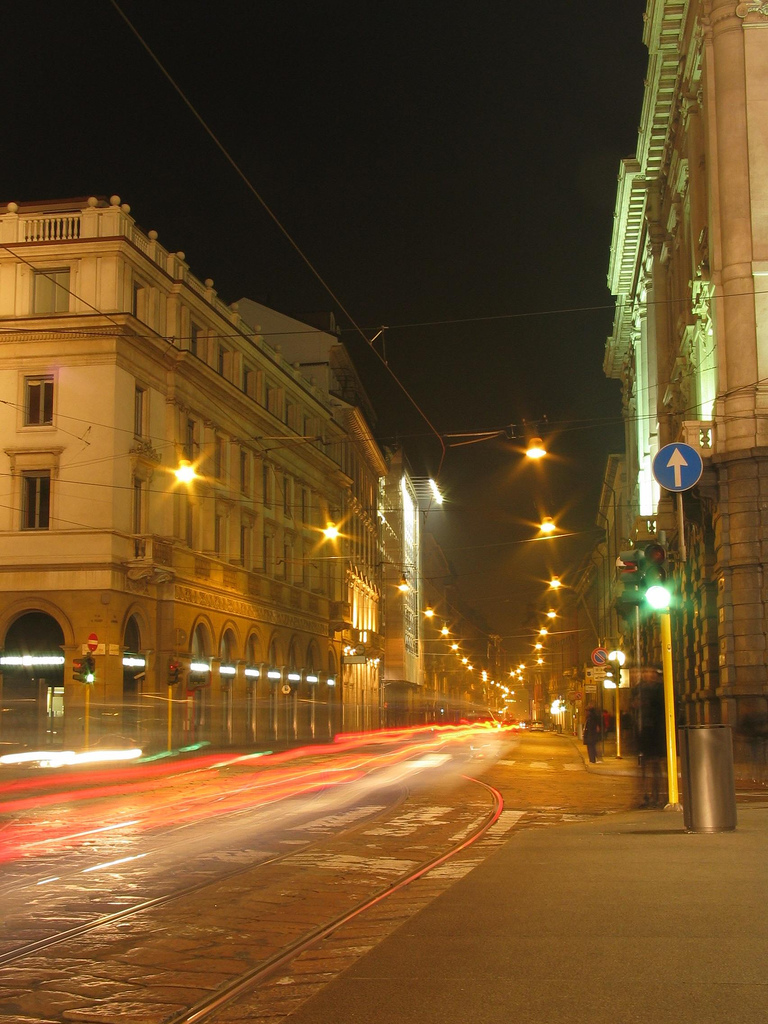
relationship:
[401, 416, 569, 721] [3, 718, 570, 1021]
street lights above street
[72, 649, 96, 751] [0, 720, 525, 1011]
stoplight on street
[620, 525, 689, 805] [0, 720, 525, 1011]
traffic light on street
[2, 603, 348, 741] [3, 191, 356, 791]
archways on building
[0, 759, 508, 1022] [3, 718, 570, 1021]
tracks on street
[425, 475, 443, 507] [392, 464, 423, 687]
lights shine on wall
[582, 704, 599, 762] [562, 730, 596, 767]
person at curb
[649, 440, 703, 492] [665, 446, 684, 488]
sign with an arrow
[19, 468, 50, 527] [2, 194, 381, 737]
window on building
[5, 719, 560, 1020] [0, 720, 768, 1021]
tracks on street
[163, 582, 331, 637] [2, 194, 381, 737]
sign on building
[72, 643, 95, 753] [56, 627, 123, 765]
stoplight on pole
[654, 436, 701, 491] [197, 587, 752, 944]
arrow points ahead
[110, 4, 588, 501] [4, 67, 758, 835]
wires in air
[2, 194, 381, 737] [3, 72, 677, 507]
building at night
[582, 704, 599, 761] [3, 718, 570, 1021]
person on street